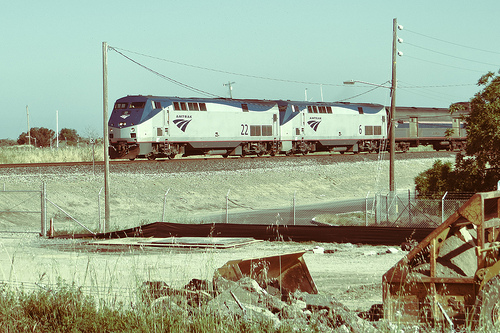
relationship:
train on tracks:
[106, 92, 499, 163] [3, 145, 497, 171]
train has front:
[106, 92, 499, 163] [100, 85, 149, 163]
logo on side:
[170, 113, 194, 131] [150, 99, 281, 143]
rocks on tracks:
[126, 161, 292, 170] [3, 145, 497, 171]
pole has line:
[101, 42, 111, 235] [105, 35, 500, 106]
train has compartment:
[106, 92, 499, 163] [405, 114, 424, 136]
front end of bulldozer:
[387, 172, 484, 320] [365, 157, 500, 331]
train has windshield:
[106, 92, 499, 163] [114, 100, 147, 112]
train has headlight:
[106, 92, 499, 163] [128, 126, 138, 137]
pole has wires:
[101, 42, 111, 235] [105, 35, 500, 106]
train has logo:
[106, 92, 499, 163] [170, 113, 194, 131]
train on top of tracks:
[106, 92, 499, 163] [3, 145, 497, 171]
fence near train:
[1, 183, 499, 242] [106, 92, 499, 163]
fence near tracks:
[1, 183, 499, 242] [3, 145, 497, 171]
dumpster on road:
[387, 172, 484, 320] [3, 230, 441, 322]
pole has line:
[101, 42, 111, 235] [105, 47, 372, 88]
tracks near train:
[3, 145, 497, 171] [106, 92, 499, 163]